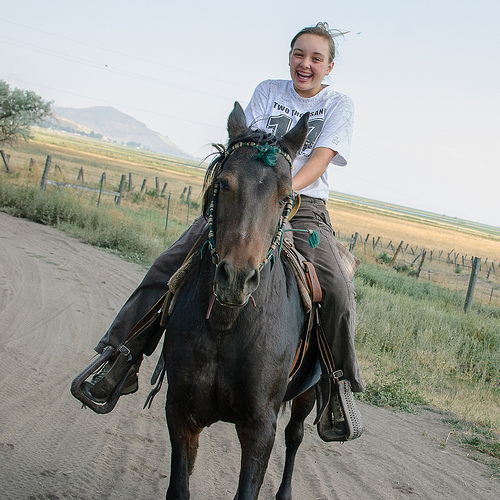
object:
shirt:
[243, 79, 356, 206]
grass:
[0, 126, 500, 479]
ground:
[0, 124, 500, 499]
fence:
[1, 148, 500, 316]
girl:
[88, 20, 364, 435]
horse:
[161, 98, 359, 500]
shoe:
[79, 359, 140, 403]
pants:
[93, 190, 366, 392]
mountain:
[32, 103, 205, 166]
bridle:
[198, 140, 323, 271]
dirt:
[0, 210, 500, 499]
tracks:
[29, 406, 116, 498]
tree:
[0, 78, 64, 152]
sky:
[0, 0, 500, 229]